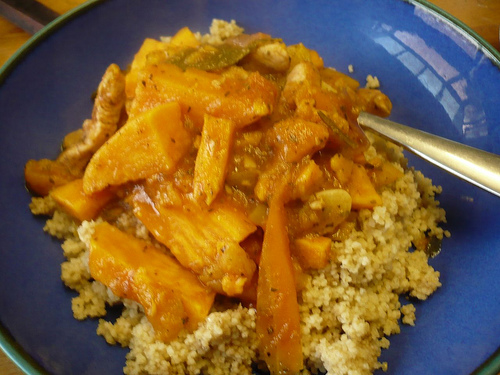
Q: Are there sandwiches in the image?
A: No, there are no sandwiches.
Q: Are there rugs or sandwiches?
A: No, there are no sandwiches or rugs.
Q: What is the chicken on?
A: The chicken is on the plate.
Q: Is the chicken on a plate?
A: Yes, the chicken is on a plate.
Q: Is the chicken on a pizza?
A: No, the chicken is on a plate.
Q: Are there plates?
A: Yes, there is a plate.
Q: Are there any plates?
A: Yes, there is a plate.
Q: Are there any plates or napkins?
A: Yes, there is a plate.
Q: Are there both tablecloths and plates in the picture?
A: No, there is a plate but no tablecloths.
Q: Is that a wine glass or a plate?
A: That is a plate.